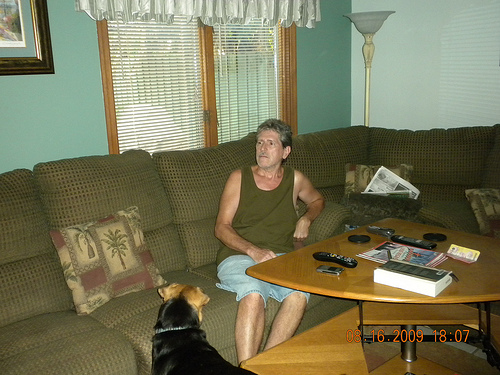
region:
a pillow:
[78, 225, 138, 289]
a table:
[271, 254, 306, 278]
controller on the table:
[313, 244, 355, 266]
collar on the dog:
[162, 321, 189, 331]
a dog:
[148, 279, 231, 373]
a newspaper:
[371, 173, 406, 194]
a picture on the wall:
[2, 24, 49, 70]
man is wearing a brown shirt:
[243, 190, 285, 225]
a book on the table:
[375, 257, 442, 299]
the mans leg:
[233, 305, 260, 358]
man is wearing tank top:
[219, 159, 306, 258]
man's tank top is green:
[213, 164, 306, 261]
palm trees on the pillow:
[49, 203, 178, 315]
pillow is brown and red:
[45, 205, 175, 317]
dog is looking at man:
[138, 114, 331, 374]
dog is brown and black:
[138, 270, 255, 372]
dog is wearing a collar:
[143, 272, 251, 373]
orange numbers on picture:
[341, 322, 475, 349]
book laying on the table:
[372, 257, 463, 302]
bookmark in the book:
[448, 268, 461, 285]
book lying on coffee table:
[369, 257, 458, 301]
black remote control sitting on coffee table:
[308, 249, 360, 270]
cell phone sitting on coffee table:
[312, 261, 346, 278]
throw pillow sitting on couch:
[46, 202, 171, 320]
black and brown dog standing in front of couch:
[148, 281, 267, 373]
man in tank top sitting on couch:
[209, 115, 329, 367]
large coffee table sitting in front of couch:
[239, 212, 498, 374]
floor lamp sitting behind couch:
[339, 4, 398, 128]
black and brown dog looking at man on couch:
[145, 279, 272, 374]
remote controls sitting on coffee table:
[365, 209, 437, 257]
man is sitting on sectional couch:
[205, 115, 327, 372]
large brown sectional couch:
[0, 117, 495, 374]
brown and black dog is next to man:
[143, 274, 260, 374]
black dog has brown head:
[142, 269, 263, 374]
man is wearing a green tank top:
[207, 103, 332, 363]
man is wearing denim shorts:
[216, 119, 330, 366]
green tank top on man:
[219, 159, 320, 259]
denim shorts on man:
[212, 247, 320, 317]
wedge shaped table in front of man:
[247, 192, 495, 327]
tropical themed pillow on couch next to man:
[41, 202, 176, 324]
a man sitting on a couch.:
[199, 105, 333, 372]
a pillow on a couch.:
[26, 137, 191, 327]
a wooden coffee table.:
[246, 208, 499, 317]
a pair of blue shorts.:
[206, 239, 317, 307]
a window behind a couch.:
[95, 0, 292, 170]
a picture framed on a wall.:
[0, 0, 63, 72]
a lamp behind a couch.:
[329, 0, 401, 128]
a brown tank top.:
[226, 146, 312, 254]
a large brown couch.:
[2, 120, 497, 373]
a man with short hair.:
[239, 105, 301, 190]